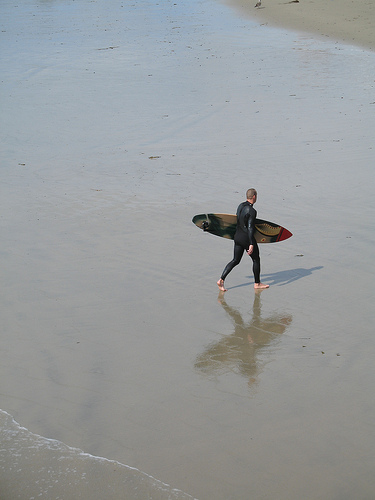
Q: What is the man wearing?
A: A wetsuit.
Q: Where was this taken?
A: At the beach.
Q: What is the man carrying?
A: A surfboard.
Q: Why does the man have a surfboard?
A: He was surfing.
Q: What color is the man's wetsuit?
A: Black.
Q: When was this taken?
A: During the day.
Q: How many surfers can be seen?
A: One.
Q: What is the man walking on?
A: Sand.